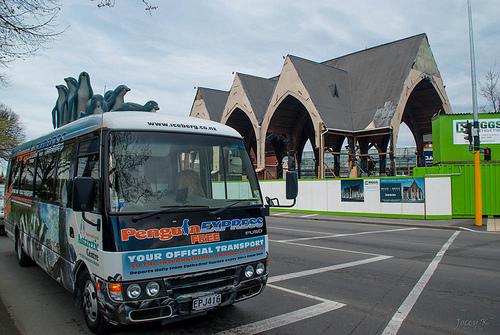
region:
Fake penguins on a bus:
[39, 70, 160, 130]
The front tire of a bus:
[76, 274, 106, 330]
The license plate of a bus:
[186, 296, 223, 311]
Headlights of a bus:
[124, 261, 271, 303]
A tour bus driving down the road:
[5, 71, 269, 325]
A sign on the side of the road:
[376, 179, 424, 203]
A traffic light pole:
[462, 4, 493, 227]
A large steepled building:
[182, 31, 454, 176]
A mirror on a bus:
[269, 170, 301, 210]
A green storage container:
[431, 112, 499, 161]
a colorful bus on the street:
[3, 70, 300, 330]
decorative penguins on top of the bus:
[51, 70, 161, 127]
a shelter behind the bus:
[187, 30, 453, 176]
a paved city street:
[2, 210, 499, 334]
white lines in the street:
[213, 223, 458, 333]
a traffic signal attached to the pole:
[461, 120, 471, 145]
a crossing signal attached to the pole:
[484, 146, 490, 159]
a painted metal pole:
[466, 0, 483, 226]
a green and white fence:
[211, 113, 499, 219]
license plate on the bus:
[192, 290, 221, 309]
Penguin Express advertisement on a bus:
[117, 218, 261, 248]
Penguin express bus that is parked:
[2, 109, 285, 326]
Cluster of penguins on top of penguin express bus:
[39, 68, 169, 126]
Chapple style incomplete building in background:
[175, 31, 452, 183]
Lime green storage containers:
[411, 108, 498, 215]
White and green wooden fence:
[259, 176, 461, 223]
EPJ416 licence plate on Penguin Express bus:
[188, 292, 230, 312]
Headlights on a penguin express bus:
[110, 258, 277, 303]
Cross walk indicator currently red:
[478, 143, 495, 166]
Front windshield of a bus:
[105, 130, 270, 217]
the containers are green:
[422, 93, 495, 222]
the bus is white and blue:
[6, 132, 259, 304]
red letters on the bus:
[117, 223, 197, 250]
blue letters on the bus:
[192, 210, 270, 236]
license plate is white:
[186, 292, 227, 320]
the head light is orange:
[89, 271, 140, 307]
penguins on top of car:
[33, 63, 160, 120]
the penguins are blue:
[47, 60, 171, 127]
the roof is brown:
[212, 51, 432, 148]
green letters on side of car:
[67, 224, 109, 255]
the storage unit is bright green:
[417, 105, 497, 216]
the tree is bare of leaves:
[1, 2, 69, 76]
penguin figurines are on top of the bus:
[45, 71, 163, 131]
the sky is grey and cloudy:
[2, 2, 497, 131]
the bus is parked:
[5, 109, 272, 328]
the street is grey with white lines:
[214, 204, 497, 333]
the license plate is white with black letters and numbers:
[190, 289, 228, 312]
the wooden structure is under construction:
[182, 32, 454, 187]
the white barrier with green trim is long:
[207, 173, 455, 223]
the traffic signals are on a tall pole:
[456, 2, 496, 231]